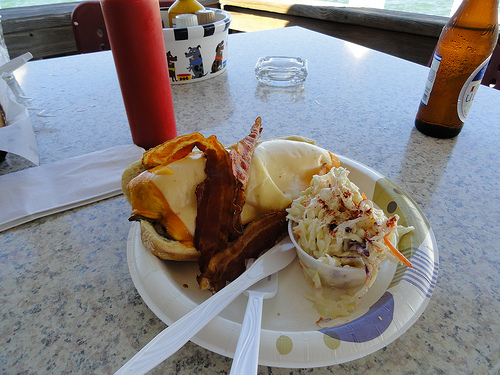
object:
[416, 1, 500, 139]
bottle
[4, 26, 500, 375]
table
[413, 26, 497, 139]
beer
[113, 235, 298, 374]
knife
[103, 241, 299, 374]
fork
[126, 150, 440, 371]
plate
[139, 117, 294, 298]
bacon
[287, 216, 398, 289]
cup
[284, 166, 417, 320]
cole slaw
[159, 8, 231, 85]
bowl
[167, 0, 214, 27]
mustard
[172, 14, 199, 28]
salt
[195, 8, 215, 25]
pepper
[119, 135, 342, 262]
sandwich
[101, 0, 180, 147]
ketchup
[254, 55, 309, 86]
ashtray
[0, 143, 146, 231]
napkin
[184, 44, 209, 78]
dog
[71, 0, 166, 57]
chair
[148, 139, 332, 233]
cheese